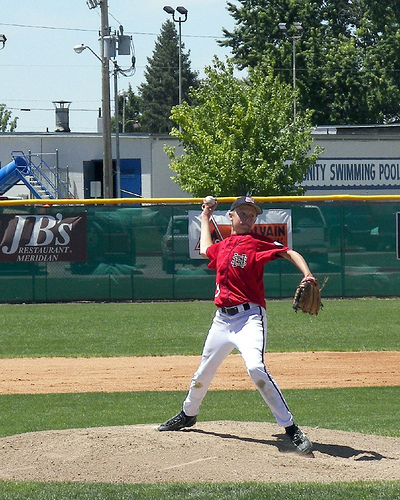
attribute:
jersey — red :
[204, 231, 289, 311]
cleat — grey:
[280, 424, 320, 458]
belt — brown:
[213, 302, 257, 320]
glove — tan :
[286, 271, 330, 321]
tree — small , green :
[149, 54, 328, 216]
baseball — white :
[195, 186, 223, 213]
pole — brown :
[91, 46, 127, 211]